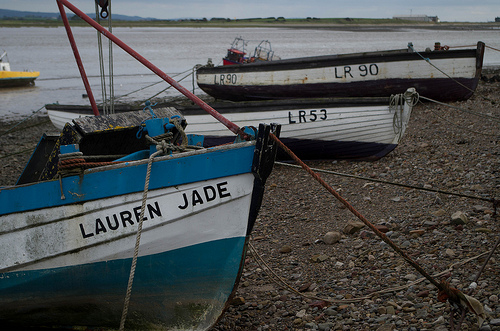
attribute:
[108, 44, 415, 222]
boats — on land, 3, small, tied up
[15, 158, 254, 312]
boat — lauren jade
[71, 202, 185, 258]
lauren — name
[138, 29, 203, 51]
water — calm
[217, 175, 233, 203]
letters — black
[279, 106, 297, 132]
letter — black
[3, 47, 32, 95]
boat — docked, docked on shore, yellow